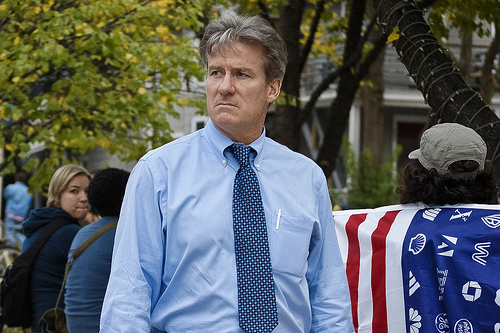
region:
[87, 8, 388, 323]
man with people in back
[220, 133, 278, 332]
tie on the man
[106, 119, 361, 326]
shirt on the man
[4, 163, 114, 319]
people sitting behind man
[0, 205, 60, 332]
black bag on woman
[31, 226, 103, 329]
greenish bag on person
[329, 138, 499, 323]
person with flag draped around him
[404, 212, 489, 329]
logos on the flag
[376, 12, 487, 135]
lights on a tree branch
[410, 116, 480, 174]
hat on man's head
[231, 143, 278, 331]
the long tie on the man's neck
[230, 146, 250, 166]
the knot on the man's tie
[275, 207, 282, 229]
the pen in the man's pocket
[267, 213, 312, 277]
the pocket on the man's shirt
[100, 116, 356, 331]
the long sleeved light blue shirt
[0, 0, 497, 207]
the trees behind the man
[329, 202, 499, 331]
the red, white and blue fabric next to the man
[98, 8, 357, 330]
the man standing and wearing a blue shirt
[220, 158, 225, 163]
the button on the man's collar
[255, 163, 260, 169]
the button on the man's collar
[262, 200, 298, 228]
A pen in the pocket.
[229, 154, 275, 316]
The man is wearing a tie.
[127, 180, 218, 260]
The shirt is blue.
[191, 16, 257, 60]
Part of the man's hair is grey.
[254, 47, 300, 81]
Part of the man's hair is brown.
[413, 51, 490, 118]
Lights wrapped around the tree branch.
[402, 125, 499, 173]
The person is wearing a hat.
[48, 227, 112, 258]
Strap across the back.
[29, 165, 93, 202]
The girl has blonde hair.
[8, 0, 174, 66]
The leaves are green and yellow.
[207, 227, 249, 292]
edge f a rie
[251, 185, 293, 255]
part of a pen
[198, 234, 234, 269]
part of a shirt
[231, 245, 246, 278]
edge of a tie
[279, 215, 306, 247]
part of a pocket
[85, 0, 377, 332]
An older man in the foreground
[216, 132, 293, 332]
Man is wearing a dotted tie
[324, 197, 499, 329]
An American flag in the background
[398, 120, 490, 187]
Person is wearing a gray cap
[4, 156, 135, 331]
Two people in the background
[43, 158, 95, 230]
Woman is looking at the camera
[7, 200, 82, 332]
Woman is wearing a dark blue hoodie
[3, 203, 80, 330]
Woman is wearing a sling bag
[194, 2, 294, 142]
Man has gray colored hair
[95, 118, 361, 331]
Man is wearing a light blue dress shirt